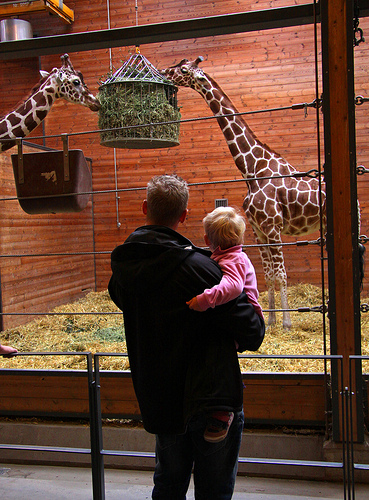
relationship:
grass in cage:
[99, 78, 180, 143] [93, 49, 182, 145]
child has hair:
[186, 206, 261, 443] [202, 204, 244, 251]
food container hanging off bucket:
[8, 136, 93, 215] [10, 149, 93, 215]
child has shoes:
[186, 206, 261, 443] [192, 381, 264, 448]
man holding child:
[106, 174, 265, 498] [186, 206, 261, 441]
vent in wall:
[215, 197, 228, 208] [0, 0, 367, 298]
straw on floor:
[30, 281, 357, 366] [1, 453, 365, 498]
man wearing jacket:
[106, 174, 265, 498] [107, 219, 269, 437]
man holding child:
[106, 174, 265, 498] [188, 202, 267, 323]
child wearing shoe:
[186, 206, 261, 441] [202, 410, 233, 441]